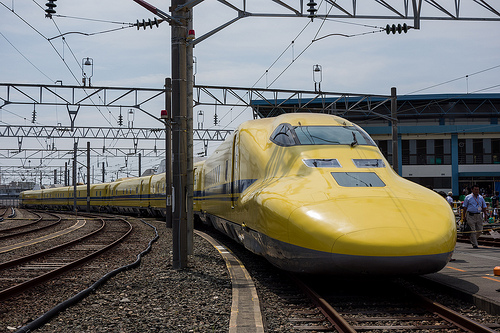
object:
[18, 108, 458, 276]
train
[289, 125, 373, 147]
windshield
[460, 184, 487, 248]
man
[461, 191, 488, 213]
shirt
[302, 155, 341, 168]
front light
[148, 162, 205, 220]
rear car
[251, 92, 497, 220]
building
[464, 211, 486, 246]
pants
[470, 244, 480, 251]
shoe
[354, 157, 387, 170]
front light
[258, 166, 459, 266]
nose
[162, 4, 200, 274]
pole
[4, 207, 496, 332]
tracks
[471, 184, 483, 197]
head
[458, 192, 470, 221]
arm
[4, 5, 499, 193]
sky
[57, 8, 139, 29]
wire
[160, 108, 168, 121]
light